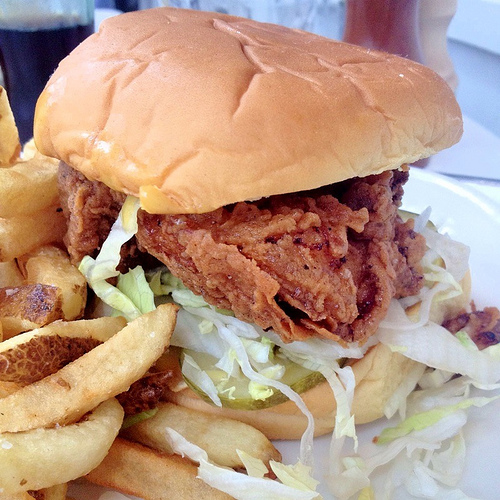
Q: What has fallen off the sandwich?
A: Lettuce.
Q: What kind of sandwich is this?
A: Chicken.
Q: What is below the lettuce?
A: Green pickle.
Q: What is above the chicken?
A: Bun.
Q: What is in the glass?
A: Soda.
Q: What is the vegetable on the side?
A: French fries.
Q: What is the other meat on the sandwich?
A: Bacon.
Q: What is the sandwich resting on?
A: Paper plate.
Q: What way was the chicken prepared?
A: Fried.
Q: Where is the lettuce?
A: On the sandwich.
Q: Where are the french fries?
A: Left of sandwich.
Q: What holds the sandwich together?
A: Buns.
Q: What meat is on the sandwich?
A: Chicken.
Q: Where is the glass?
A: Behind the food.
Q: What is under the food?
A: A plate.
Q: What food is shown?
A: Sandwich and fries.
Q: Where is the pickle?
A: Beneath the lettuce.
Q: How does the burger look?
A: Delicious.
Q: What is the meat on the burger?
A: Chicken.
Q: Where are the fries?
A: Near the burger.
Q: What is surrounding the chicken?
A: Bread.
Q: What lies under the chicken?
A: Lettuce.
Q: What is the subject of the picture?
A: A burger.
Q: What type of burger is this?
A: Chicken burger.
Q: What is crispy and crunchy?
A: Bacon slices.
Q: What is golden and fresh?
A: French fries.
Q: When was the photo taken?
A: Daytime.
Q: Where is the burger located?
A: A plate.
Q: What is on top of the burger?
A: Bacon.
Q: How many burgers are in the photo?
A: One.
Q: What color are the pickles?
A: Green.